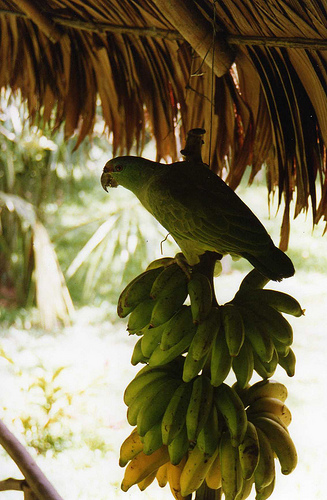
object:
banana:
[190, 264, 212, 324]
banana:
[209, 383, 248, 447]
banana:
[120, 445, 170, 491]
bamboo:
[155, 0, 233, 78]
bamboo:
[13, 1, 62, 42]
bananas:
[124, 368, 166, 406]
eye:
[109, 163, 116, 171]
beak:
[100, 178, 109, 193]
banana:
[167, 454, 188, 499]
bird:
[101, 152, 295, 282]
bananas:
[120, 444, 169, 492]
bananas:
[155, 461, 168, 488]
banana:
[161, 306, 194, 351]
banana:
[226, 305, 246, 359]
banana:
[188, 312, 218, 363]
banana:
[278, 348, 296, 377]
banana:
[258, 428, 275, 489]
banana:
[148, 337, 193, 368]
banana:
[186, 382, 208, 446]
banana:
[240, 288, 306, 317]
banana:
[180, 443, 219, 496]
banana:
[162, 383, 192, 446]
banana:
[117, 270, 149, 318]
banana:
[255, 417, 298, 475]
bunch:
[150, 388, 242, 432]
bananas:
[126, 378, 163, 426]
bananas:
[136, 382, 179, 437]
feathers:
[140, 161, 295, 282]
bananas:
[118, 426, 143, 468]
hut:
[1, 1, 327, 236]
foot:
[164, 253, 191, 279]